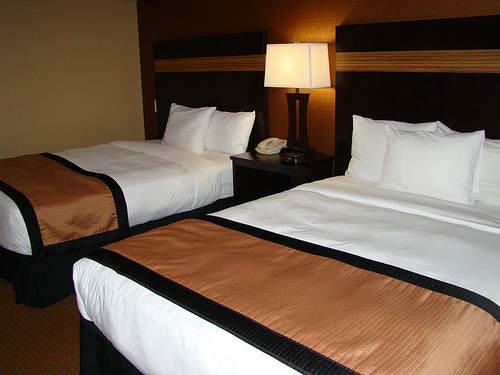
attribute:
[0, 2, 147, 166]
wall — tan, Beige, yellow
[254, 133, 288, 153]
phone — land line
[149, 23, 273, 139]
headboard — black, Brown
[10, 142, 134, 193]
bed — brown, black, white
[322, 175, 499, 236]
sheets — white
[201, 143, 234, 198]
sheets — white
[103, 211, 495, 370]
runner — gold, black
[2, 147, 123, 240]
runner — gold, black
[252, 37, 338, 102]
lampshade — illuminated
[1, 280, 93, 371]
floor — brown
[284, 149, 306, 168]
clock — black, red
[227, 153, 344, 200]
stand — night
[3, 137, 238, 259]
white sheets — clean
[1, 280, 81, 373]
floor — carpeted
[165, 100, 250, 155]
pillows — white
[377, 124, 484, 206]
pillow — white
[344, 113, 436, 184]
pillow — white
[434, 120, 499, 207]
pillow — white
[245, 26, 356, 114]
lamp shade — white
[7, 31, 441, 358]
room — hotel room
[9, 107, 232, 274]
bed — hotel bed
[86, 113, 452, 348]
bed — hotel bed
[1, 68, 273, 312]
bed — white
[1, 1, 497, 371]
bedroom — hotel bedroom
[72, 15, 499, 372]
bed — hotel bed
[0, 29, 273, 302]
bed — hotel bed